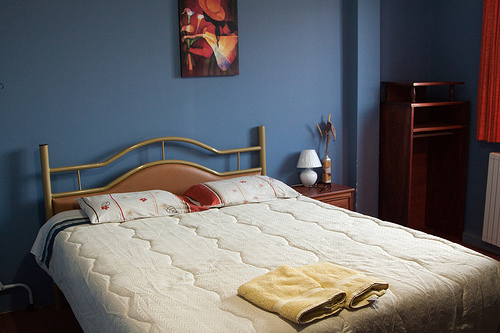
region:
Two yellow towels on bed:
[233, 260, 390, 329]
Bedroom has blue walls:
[1, 38, 498, 282]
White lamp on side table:
[298, 144, 320, 189]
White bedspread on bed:
[28, 177, 497, 328]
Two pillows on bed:
[76, 171, 300, 226]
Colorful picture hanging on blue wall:
[178, 0, 240, 80]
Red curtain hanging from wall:
[478, 3, 497, 148]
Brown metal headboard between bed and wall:
[38, 124, 265, 224]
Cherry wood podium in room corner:
[377, 76, 473, 256]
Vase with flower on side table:
[315, 112, 338, 188]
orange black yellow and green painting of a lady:
[173, 1, 243, 77]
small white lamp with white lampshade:
[295, 147, 322, 186]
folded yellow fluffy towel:
[235, 262, 342, 324]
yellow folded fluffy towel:
[296, 260, 386, 306]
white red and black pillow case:
[80, 191, 190, 218]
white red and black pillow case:
[191, 170, 292, 206]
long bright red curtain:
[475, 1, 498, 147]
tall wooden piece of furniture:
[377, 76, 472, 233]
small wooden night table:
[286, 182, 353, 207]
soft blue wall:
[2, 1, 483, 274]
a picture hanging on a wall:
[121, 2, 253, 92]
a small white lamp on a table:
[283, 146, 325, 203]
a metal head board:
[23, 102, 280, 231]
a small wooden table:
[290, 175, 356, 210]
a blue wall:
[15, 22, 320, 135]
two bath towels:
[242, 253, 392, 328]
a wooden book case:
[390, 65, 472, 206]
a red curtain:
[470, 17, 496, 156]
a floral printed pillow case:
[67, 177, 183, 232]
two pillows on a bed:
[77, 156, 279, 246]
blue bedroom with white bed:
[23, 115, 483, 312]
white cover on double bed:
[48, 254, 219, 311]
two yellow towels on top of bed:
[219, 249, 391, 302]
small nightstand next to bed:
[266, 184, 371, 219]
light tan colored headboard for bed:
[30, 126, 275, 201]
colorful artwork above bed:
[162, 0, 261, 84]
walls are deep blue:
[37, 22, 144, 115]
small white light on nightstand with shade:
[284, 141, 323, 200]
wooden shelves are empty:
[374, 38, 471, 240]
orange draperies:
[455, 1, 493, 154]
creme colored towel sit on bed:
[236, 255, 391, 322]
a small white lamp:
[298, 149, 319, 184]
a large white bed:
[29, 180, 489, 332]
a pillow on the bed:
[76, 195, 193, 217]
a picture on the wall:
[179, 5, 240, 75]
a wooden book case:
[388, 80, 467, 229]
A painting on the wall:
[170, 0, 245, 85]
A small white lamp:
[290, 140, 325, 190]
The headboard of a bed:
[30, 115, 270, 225]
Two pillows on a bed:
[65, 165, 310, 225]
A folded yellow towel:
[226, 255, 391, 330]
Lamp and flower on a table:
[276, 105, 362, 216]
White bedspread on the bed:
[21, 170, 496, 330]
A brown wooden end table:
[276, 175, 356, 215]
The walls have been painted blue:
[0, 0, 495, 320]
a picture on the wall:
[170, 7, 239, 77]